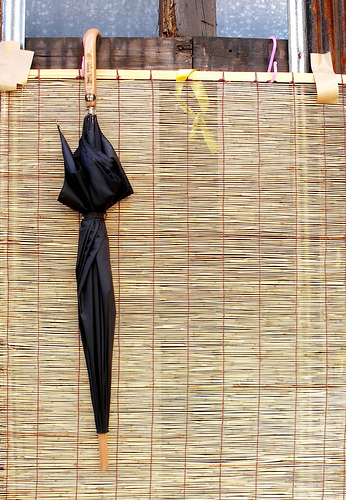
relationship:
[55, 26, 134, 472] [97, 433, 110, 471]
black umbrella has tip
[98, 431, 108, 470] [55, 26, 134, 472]
tip of black umbrella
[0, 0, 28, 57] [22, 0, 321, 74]
siding on window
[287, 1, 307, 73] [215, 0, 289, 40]
siding on window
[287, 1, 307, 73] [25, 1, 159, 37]
siding on window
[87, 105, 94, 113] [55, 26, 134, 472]
metal rod inside black umbrella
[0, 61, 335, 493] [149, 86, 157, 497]
bamboo has twine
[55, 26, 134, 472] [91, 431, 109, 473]
black umbrella has tip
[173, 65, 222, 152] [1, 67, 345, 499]
ribbon on shade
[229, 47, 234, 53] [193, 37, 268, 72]
nail holds wood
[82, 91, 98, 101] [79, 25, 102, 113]
sticker on handle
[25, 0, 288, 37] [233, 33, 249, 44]
window has edge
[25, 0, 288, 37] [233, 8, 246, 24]
window seen part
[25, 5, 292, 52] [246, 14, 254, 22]
window has side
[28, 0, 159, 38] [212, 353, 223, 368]
pane has edge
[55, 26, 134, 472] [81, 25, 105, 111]
black umbrella has handle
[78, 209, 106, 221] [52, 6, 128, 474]
black strap around black umbrella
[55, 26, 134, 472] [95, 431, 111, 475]
black umbrella has tip